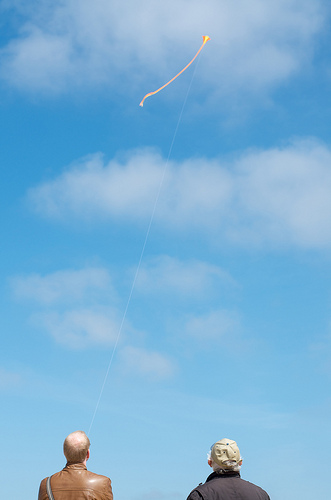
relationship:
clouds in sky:
[2, 2, 328, 469] [0, 0, 331, 498]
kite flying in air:
[137, 31, 219, 114] [5, 5, 328, 423]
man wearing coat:
[186, 439, 270, 498] [185, 471, 268, 498]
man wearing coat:
[37, 429, 112, 498] [38, 467, 129, 498]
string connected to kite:
[114, 79, 207, 237] [103, 21, 256, 130]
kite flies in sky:
[138, 35, 210, 109] [14, 72, 302, 387]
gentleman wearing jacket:
[35, 429, 113, 498] [19, 407, 115, 498]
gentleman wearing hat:
[171, 425, 298, 498] [201, 438, 244, 466]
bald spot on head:
[65, 431, 87, 452] [57, 432, 143, 464]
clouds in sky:
[30, 138, 320, 256] [0, 0, 331, 498]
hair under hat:
[213, 466, 241, 471] [212, 437, 244, 473]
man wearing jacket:
[37, 429, 112, 498] [37, 460, 113, 498]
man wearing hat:
[186, 439, 270, 498] [208, 436, 242, 470]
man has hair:
[186, 439, 270, 498] [207, 450, 240, 470]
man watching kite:
[186, 439, 270, 498] [138, 35, 210, 109]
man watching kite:
[36, 426, 113, 495] [138, 35, 210, 109]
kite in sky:
[138, 35, 210, 109] [0, 0, 331, 498]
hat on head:
[205, 438, 246, 473] [203, 436, 246, 473]